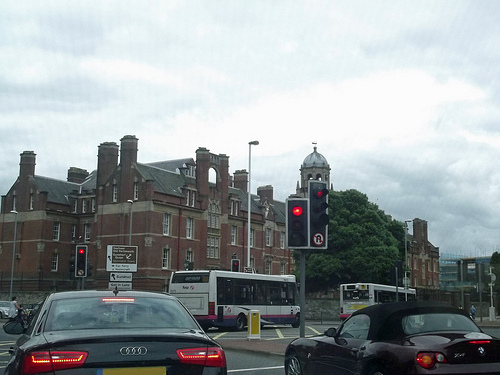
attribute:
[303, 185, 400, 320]
tree — green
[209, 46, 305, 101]
sky — cloudy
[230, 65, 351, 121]
sky — cloudy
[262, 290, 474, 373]
car — black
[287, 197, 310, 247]
traffic light — red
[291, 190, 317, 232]
light — red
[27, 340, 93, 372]
rear light — red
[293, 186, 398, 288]
trees — green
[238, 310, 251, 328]
tire — back tire